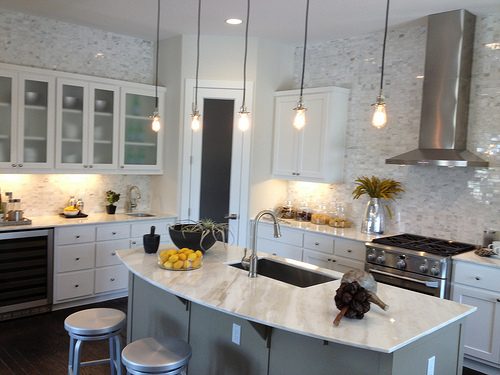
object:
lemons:
[168, 254, 179, 262]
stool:
[63, 307, 128, 375]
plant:
[166, 217, 235, 253]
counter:
[114, 239, 479, 375]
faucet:
[248, 210, 283, 279]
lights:
[151, 116, 161, 133]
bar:
[0, 0, 500, 375]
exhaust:
[383, 8, 489, 168]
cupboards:
[0, 62, 166, 177]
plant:
[351, 174, 405, 220]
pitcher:
[360, 197, 386, 235]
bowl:
[142, 233, 160, 254]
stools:
[119, 335, 192, 375]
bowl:
[157, 254, 204, 271]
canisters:
[276, 197, 298, 221]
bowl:
[168, 223, 222, 255]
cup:
[488, 240, 500, 254]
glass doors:
[119, 87, 165, 170]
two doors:
[272, 93, 329, 179]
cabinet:
[268, 86, 351, 185]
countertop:
[248, 210, 500, 267]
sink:
[225, 257, 340, 289]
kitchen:
[0, 0, 499, 374]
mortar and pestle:
[142, 225, 160, 254]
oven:
[363, 232, 476, 299]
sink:
[126, 212, 155, 218]